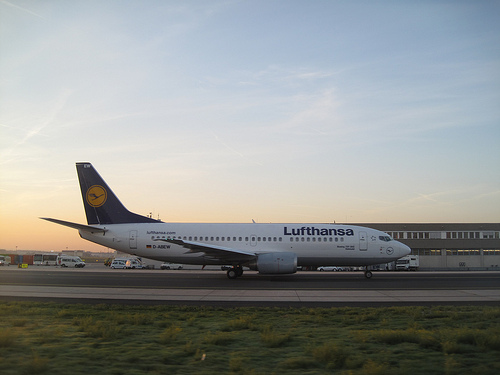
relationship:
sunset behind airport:
[4, 211, 95, 256] [359, 216, 497, 257]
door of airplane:
[358, 230, 367, 250] [40, 162, 411, 279]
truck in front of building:
[347, 256, 422, 271] [342, 220, 495, 273]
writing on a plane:
[283, 223, 356, 240] [50, 146, 430, 274]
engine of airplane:
[254, 250, 299, 275] [40, 162, 411, 279]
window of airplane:
[376, 227, 402, 241] [40, 162, 411, 279]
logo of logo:
[283, 224, 353, 234] [284, 227, 354, 236]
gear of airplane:
[350, 264, 380, 284] [40, 162, 411, 279]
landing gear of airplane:
[225, 267, 237, 277] [40, 162, 411, 279]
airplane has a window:
[40, 162, 411, 279] [340, 235, 347, 242]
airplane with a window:
[40, 162, 411, 279] [320, 238, 327, 244]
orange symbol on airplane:
[86, 185, 108, 208] [40, 162, 411, 279]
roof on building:
[316, 220, 493, 247] [366, 220, 499, 273]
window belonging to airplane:
[377, 227, 400, 243] [40, 162, 411, 279]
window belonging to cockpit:
[377, 227, 400, 243] [370, 229, 398, 247]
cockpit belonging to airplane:
[370, 229, 398, 247] [40, 162, 411, 279]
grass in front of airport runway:
[0, 301, 498, 373] [1, 267, 500, 305]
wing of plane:
[159, 230, 269, 271] [73, 195, 389, 275]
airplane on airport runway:
[40, 162, 411, 279] [1, 267, 500, 305]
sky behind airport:
[2, 1, 498, 248] [3, 2, 496, 372]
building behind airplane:
[318, 219, 498, 273] [40, 162, 411, 279]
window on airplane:
[376, 232, 391, 242] [40, 162, 411, 279]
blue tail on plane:
[63, 155, 168, 227] [59, 194, 416, 312]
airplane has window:
[37, 152, 421, 280] [335, 234, 344, 244]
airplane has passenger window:
[37, 152, 421, 280] [338, 234, 345, 244]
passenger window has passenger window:
[338, 234, 345, 244] [288, 237, 293, 242]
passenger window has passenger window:
[338, 234, 345, 244] [327, 236, 332, 242]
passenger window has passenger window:
[338, 234, 345, 244] [305, 235, 311, 243]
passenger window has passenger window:
[338, 234, 345, 244] [300, 235, 305, 242]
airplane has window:
[40, 162, 411, 279] [250, 232, 255, 241]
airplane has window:
[40, 162, 411, 279] [275, 235, 284, 242]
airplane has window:
[40, 162, 411, 279] [286, 234, 295, 244]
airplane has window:
[40, 162, 411, 279] [338, 235, 345, 243]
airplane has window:
[40, 162, 411, 279] [310, 235, 317, 243]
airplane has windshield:
[40, 162, 411, 279] [380, 236, 391, 241]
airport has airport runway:
[3, 153, 473, 312] [1, 264, 498, 306]